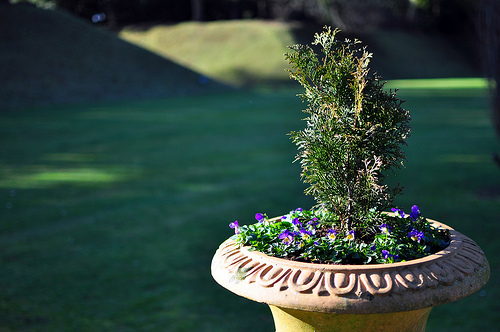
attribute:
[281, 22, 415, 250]
plant — planting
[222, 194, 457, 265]
flowers — purple, little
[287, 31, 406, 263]
shrub — green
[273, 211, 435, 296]
soil — for potting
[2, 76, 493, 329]
lawn — green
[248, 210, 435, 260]
center — area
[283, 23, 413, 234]
green plant — single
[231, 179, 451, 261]
flowers — blue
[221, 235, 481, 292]
pattern — fancy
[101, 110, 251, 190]
grass — vibrant, green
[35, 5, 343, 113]
hill — slanted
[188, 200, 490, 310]
planter — scalloped edged, fancy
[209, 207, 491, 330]
flower pot — fancy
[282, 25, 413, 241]
bush — small, green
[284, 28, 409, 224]
bush — green, small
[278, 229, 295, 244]
flower — purple, small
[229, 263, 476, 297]
design — on top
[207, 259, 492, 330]
holder — for plant